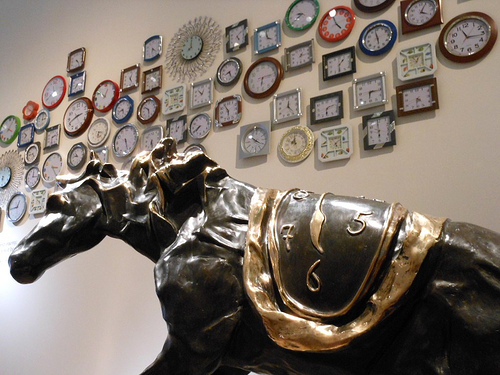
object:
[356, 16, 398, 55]
clock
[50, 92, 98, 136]
clock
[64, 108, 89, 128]
dials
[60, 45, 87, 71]
clock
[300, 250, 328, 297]
numbers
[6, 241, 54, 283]
nose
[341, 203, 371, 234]
5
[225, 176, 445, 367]
saddle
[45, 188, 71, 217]
eye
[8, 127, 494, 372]
horse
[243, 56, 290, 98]
clock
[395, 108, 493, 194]
wall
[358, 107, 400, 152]
clock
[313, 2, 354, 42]
clock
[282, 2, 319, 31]
clock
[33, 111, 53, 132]
clock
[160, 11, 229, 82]
clock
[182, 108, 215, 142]
clock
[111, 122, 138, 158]
clock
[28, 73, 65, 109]
clock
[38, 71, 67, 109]
frame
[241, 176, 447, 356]
clock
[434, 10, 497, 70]
frame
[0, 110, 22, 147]
clock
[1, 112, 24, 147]
frame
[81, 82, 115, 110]
clock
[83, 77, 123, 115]
frame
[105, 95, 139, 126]
frame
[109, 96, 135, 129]
clock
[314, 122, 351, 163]
clock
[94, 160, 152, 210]
mane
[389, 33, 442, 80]
clock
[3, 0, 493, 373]
room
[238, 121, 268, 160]
clocks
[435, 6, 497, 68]
clock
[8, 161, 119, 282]
head